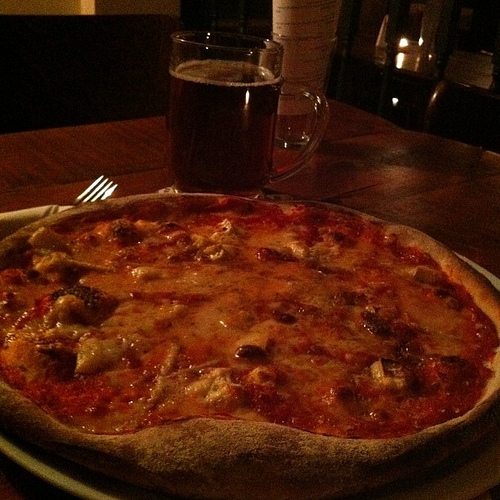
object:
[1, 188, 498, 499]
dish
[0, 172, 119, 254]
fork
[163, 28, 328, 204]
glass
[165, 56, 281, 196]
beer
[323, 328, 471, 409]
sauce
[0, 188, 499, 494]
crust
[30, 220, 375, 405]
vegetables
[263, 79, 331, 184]
handle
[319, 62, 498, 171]
table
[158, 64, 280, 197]
wine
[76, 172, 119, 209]
top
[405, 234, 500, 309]
edge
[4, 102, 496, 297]
top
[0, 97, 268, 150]
edge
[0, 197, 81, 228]
wrap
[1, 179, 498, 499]
pizza